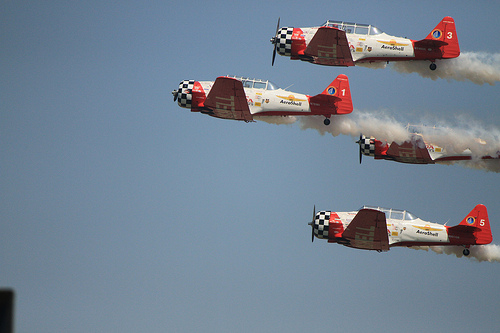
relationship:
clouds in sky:
[299, 88, 494, 162] [5, 3, 495, 327]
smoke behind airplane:
[238, 104, 496, 160] [172, 74, 354, 126]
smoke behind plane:
[411, 240, 498, 262] [307, 202, 491, 250]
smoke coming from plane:
[253, 107, 498, 163] [168, 70, 356, 126]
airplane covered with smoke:
[355, 131, 500, 165] [298, 107, 499, 174]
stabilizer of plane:
[449, 222, 480, 239] [310, 202, 492, 245]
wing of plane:
[350, 209, 407, 237] [294, 186, 498, 276]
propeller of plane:
[304, 198, 317, 244] [297, 191, 493, 263]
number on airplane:
[348, 215, 379, 241] [308, 203, 492, 256]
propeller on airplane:
[264, 16, 288, 65] [270, 16, 460, 71]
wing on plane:
[297, 19, 358, 71] [263, 13, 463, 76]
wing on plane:
[197, 73, 261, 125] [167, 72, 359, 130]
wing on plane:
[376, 130, 437, 168] [350, 117, 500, 169]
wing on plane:
[342, 208, 390, 245] [304, 202, 500, 259]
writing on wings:
[209, 88, 239, 122] [200, 68, 255, 125]